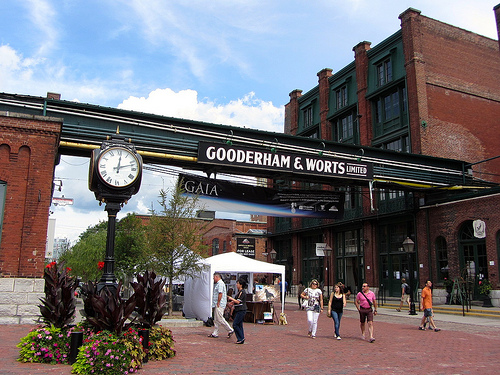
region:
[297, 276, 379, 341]
people walking through an outdoor shopping center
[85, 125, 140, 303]
a tall clock in an outdoor shopping center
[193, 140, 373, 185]
A Gooderham & Worts Limited advertising sign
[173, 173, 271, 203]
A Gaia advertising sign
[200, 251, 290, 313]
a large outdoor tent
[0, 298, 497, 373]
a tile walking area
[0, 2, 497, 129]
a partially cloudy sky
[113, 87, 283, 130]
a fluffy white cloud in the sky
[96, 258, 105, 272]
a beautiful red flower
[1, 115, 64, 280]
a red brick building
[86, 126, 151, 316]
a clock on a pole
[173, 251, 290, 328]
a tent on the side walk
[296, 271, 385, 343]
people walking on the side walk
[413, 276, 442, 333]
a man in a orange shirt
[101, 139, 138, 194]
the face of a clock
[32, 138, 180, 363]
flowers around a clock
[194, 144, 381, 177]
writing on a sign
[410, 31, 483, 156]
a brick building wall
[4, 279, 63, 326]
concerte border on building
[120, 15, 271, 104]
clouds in the sky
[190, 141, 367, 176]
white letters on bridge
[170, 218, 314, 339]
white tent below sign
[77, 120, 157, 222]
black and white clock post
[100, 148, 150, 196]
roman numerals on clock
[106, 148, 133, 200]
black hands on clock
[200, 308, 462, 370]
red brick on sidewalk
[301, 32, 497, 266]
tall red building behind people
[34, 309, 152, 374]
green bushes under clock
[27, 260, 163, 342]
red flowering plants below clock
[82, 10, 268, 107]
sky is blue with few clouds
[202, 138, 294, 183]
A sign with the word "Gooderham" Printed on it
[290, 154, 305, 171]
A sign with the phrase "&" Printed on it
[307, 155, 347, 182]
A sign with the word "Worts" Printed on it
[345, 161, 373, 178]
A sign with the word "United" Printed on it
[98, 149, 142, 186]
The face of a clock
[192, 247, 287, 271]
The roof of a white tent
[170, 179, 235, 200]
A sign with the word "Gaia" Printed on it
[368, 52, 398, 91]
A window at the top of a building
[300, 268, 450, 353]
A group of people walking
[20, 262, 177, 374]
Agroup of bushes and shrubberies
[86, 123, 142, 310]
Black and white clock on post.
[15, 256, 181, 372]
Flowers and plants surrounding the clock.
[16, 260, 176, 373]
An arrangement of different flowers and plants.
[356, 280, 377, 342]
A man wearing a pink shirt.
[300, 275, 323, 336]
A woman wearing white pants.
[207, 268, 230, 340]
A man wearing beige pants.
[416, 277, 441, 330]
A man wearing an orange top.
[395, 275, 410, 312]
A man carrying a black bookbag.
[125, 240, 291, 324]
White tents lined up on the street.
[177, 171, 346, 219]
A banner that has 'GAIA' written on it.